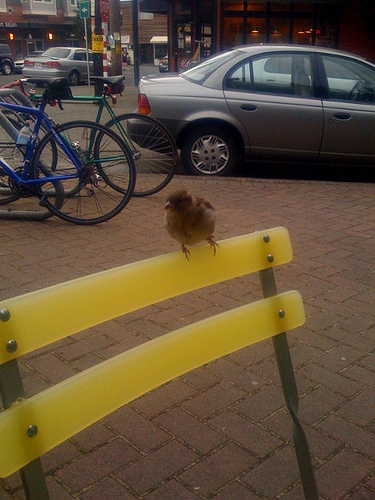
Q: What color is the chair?
A: Yellow and Gray.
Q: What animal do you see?
A: Bird.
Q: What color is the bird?
A: Tan.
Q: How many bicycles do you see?
A: 2.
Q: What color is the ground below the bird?
A: Brown.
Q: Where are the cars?
A: Behind the bird.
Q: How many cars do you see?
A: 6.